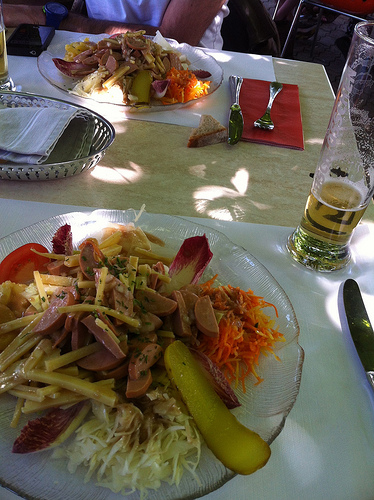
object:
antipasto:
[0, 222, 285, 498]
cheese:
[57, 403, 200, 499]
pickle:
[164, 340, 271, 476]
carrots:
[198, 274, 286, 394]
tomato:
[0, 242, 50, 283]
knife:
[337, 279, 373, 404]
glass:
[284, 21, 374, 274]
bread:
[187, 115, 228, 148]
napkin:
[239, 78, 304, 150]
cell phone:
[5, 23, 55, 58]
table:
[0, 25, 373, 500]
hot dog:
[33, 238, 219, 398]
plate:
[52, 30, 210, 107]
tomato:
[52, 57, 96, 78]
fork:
[253, 81, 283, 130]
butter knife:
[228, 102, 244, 145]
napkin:
[0, 108, 95, 165]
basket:
[0, 91, 116, 181]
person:
[1, 0, 227, 47]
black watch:
[41, 1, 67, 29]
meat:
[54, 27, 210, 110]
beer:
[286, 175, 373, 271]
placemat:
[0, 193, 373, 499]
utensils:
[227, 75, 303, 151]